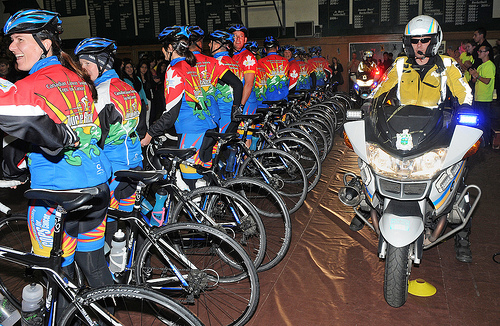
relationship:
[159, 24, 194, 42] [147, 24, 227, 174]
helmet on cyclist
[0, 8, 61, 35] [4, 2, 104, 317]
helmet on cyclist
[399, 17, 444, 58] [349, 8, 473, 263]
helmet on biker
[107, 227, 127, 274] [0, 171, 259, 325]
water bottle on a bicycle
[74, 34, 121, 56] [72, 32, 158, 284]
helmet on cyclist